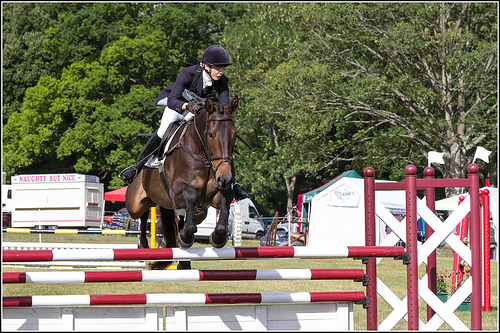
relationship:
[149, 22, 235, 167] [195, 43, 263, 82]
woman in black hat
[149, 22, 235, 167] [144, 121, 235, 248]
woman on horse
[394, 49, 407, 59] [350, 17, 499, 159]
leaves on trees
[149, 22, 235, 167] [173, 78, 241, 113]
woman in black jacket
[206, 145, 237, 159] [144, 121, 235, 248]
harness on horse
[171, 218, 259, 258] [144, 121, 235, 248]
hooves on horse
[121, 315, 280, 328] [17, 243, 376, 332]
base of fence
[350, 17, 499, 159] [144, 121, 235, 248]
trees behind horse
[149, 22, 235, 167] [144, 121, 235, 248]
woman riding horse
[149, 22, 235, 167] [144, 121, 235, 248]
woman riding with horse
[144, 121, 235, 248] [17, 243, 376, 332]
horse jumping fence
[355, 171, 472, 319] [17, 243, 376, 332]
scaffolding holding fence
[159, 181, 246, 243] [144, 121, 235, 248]
legs of horse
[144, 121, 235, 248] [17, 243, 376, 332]
horse jumping over fence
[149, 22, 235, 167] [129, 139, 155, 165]
woman in boots